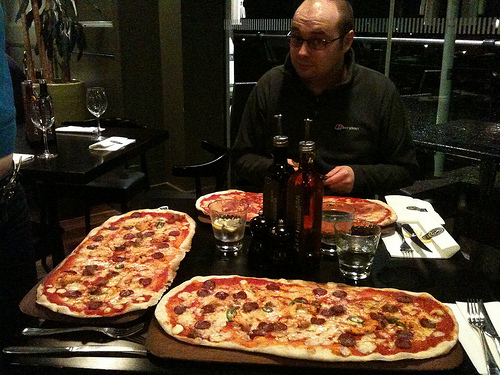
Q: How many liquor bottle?
A: Two.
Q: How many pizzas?
A: Three.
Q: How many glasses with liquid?
A: 3.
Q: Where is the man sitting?
A: At the table.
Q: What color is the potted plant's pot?
A: Green.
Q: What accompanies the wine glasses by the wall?
A: Napkins.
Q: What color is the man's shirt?
A: Green.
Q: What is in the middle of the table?
A: Oil and vinegar.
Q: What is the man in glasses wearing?
A: Green jacket.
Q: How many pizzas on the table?
A: 3.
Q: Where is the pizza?
A: On the table.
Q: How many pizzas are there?
A: 3.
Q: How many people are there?
A: 1.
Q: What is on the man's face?
A: Glasses.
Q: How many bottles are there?
A: 2.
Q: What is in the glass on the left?
A: Lemons.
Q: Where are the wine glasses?
A: On the table next to the man.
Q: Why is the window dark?
A: The sun went down.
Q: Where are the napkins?
A: Under the silverware.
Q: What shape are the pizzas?
A: Oval.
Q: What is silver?
A: Utensils.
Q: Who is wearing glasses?
A: The man.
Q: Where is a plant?
A: In a pot.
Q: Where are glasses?
A: On the table.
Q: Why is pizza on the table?
A: To be eaten.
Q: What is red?
A: Tomato sauce.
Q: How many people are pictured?
A: One.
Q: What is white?
A: Napkins.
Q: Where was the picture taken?
A: In a pizzaria`.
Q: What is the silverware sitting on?
A: Napkins.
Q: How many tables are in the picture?
A: Two.